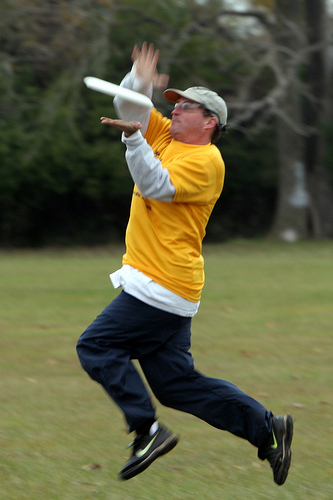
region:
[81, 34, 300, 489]
Man jumping into the air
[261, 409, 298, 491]
Black Nike tennis shoes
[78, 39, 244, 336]
Man catching a frisbee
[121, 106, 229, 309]
A bright yellow shirt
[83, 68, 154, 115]
A frisbee flying through the air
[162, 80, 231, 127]
A tan colored baseball cap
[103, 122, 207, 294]
man wearing a yellow shirt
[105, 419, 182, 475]
man wearing black shoes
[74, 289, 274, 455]
man wearing blue pants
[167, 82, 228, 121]
man wearing a brown hat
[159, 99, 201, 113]
man wearing safety goggles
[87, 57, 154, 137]
man catching a frisbee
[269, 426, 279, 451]
Nike logo on a black shoe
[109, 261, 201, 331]
white shirt under a yellow shirt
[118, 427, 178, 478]
A black shoe on a man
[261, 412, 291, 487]
A black shoe on a man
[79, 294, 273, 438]
Dark blue pants on a man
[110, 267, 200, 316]
A white shirt under a yellow shirt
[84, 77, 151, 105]
A white frisbee in the air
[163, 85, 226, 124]
A cap on a man's head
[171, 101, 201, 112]
Glasses on a man's face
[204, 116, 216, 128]
An ear on a man's head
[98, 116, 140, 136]
A man's hand under a frisbee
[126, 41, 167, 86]
A man's hand above a frisbee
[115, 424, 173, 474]
man wearing black sneakers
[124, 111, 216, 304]
man wearing a yellow tee shirt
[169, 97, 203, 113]
man wearing safety goggles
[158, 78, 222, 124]
man wearing a brown hat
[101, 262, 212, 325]
man wearing a white tee shirt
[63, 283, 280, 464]
man wearing blue pants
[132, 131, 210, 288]
man wearing a yellow shirt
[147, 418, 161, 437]
man wearing white socks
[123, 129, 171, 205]
gray sleeve for the shirt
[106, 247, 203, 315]
white shirt tails under the yellow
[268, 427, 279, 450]
a green check mark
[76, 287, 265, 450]
loose fitting navy blue slacks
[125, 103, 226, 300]
bright yellow t-shirt over white shirt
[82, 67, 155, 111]
white frisbee about to be caught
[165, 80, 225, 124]
a sage green cap with red under visor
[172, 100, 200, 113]
metal framed eyeglasses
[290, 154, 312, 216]
a target for frisbee golf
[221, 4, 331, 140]
bare limbs of a tree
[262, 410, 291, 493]
black sneaker with a white stripe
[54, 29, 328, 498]
this is a man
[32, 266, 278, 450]
man wearing blue pants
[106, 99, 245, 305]
man wearing a yellow shirt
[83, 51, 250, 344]
man wear two shirts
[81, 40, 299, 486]
man wearing yellow shirt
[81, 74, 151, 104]
white frisbee the man is catching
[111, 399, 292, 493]
black shoes the man is wearing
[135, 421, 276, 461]
nike logo on the shoes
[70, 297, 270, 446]
navy pants the man is wearing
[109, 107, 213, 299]
yellow short sleeve shirt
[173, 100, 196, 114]
glasses the man is wearing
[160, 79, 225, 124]
hat the man is wearing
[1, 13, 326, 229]
trees behind the man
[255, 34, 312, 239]
large tree trunk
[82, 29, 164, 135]
hands grabbing at the white frisbee